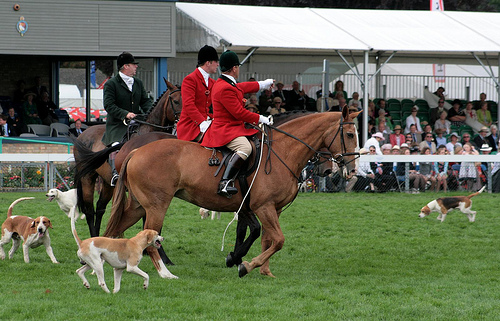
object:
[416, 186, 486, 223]
dog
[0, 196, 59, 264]
dog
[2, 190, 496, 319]
grass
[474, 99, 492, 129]
woman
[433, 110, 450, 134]
woman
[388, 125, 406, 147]
woman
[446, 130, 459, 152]
woman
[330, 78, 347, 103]
woman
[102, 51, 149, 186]
man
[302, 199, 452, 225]
ground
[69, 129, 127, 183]
tail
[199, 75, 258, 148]
coats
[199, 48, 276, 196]
man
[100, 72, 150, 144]
jacket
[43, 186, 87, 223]
dog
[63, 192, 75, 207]
dog's coat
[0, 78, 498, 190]
spectators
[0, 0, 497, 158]
background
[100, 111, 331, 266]
horse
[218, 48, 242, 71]
black hat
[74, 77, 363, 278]
people horses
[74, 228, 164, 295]
dog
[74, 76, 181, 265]
horse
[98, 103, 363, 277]
brown horse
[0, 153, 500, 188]
fence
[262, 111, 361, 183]
reins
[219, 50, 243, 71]
hat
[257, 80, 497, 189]
people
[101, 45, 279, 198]
people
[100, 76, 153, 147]
coat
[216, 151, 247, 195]
boot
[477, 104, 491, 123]
vest